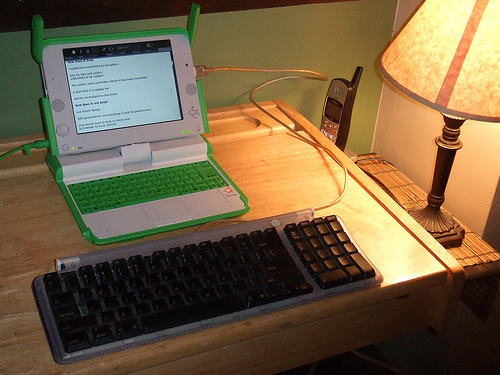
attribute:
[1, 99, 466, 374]
desk — wood, wooden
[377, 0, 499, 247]
lamp — on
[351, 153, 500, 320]
table — brown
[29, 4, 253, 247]
laptop — green, white, gray, small, old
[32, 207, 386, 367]
keyboard — black, old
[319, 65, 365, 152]
telephone — cordless, silver, black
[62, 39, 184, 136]
screen — on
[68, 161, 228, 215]
keyboard — green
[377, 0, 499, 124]
lamp shade — beige, white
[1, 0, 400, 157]
wall — green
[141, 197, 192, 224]
touchpad — white